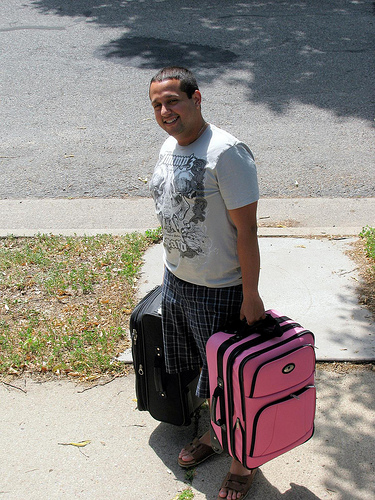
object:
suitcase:
[130, 285, 206, 426]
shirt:
[149, 124, 259, 288]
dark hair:
[151, 66, 199, 99]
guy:
[150, 66, 265, 499]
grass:
[176, 485, 194, 499]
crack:
[183, 407, 200, 499]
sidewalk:
[0, 0, 375, 500]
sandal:
[177, 436, 215, 469]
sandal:
[215, 469, 257, 499]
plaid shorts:
[161, 265, 242, 399]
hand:
[240, 296, 266, 325]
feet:
[178, 429, 215, 461]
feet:
[219, 458, 252, 498]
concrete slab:
[0, 230, 162, 381]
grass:
[45, 299, 112, 373]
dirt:
[4, 266, 85, 360]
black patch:
[92, 29, 238, 83]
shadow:
[20, 0, 373, 128]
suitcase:
[206, 317, 318, 470]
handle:
[221, 314, 281, 338]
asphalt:
[0, 0, 375, 229]